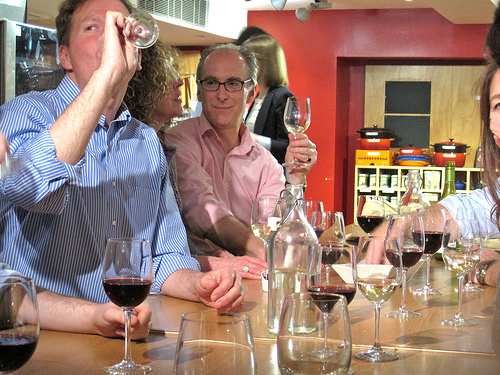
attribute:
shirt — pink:
[163, 112, 290, 242]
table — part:
[398, 328, 495, 370]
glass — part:
[115, 5, 160, 50]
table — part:
[0, 215, 499, 371]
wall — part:
[313, 12, 480, 121]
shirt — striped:
[4, 69, 203, 298]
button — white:
[106, 173, 125, 190]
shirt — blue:
[1, 66, 218, 313]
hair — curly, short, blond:
[124, 38, 187, 144]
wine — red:
[104, 277, 150, 308]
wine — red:
[307, 283, 354, 313]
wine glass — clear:
[274, 95, 315, 132]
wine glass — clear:
[174, 306, 255, 373]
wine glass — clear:
[97, 235, 157, 305]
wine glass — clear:
[353, 231, 398, 363]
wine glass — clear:
[441, 213, 484, 328]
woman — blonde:
[128, 34, 270, 279]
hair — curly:
[122, 37, 182, 127]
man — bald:
[163, 42, 315, 263]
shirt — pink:
[163, 111, 288, 261]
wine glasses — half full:
[298, 191, 450, 360]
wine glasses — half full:
[102, 235, 154, 373]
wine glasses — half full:
[0, 270, 40, 374]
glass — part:
[308, 243, 360, 331]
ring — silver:
[231, 263, 249, 283]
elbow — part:
[4, 150, 79, 214]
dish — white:
[334, 249, 401, 289]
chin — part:
[210, 118, 222, 128]